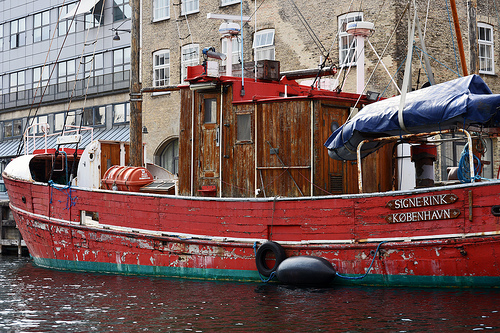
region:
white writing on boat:
[392, 193, 447, 207]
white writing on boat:
[390, 207, 449, 222]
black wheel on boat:
[254, 242, 282, 276]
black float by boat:
[272, 255, 335, 289]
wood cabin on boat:
[177, 73, 387, 198]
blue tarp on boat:
[322, 74, 497, 167]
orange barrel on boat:
[101, 164, 149, 192]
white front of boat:
[75, 140, 105, 194]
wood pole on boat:
[128, 2, 143, 169]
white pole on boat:
[344, 22, 374, 94]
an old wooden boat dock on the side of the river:
[11, 62, 495, 310]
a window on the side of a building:
[8, 19, 24, 49]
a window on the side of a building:
[35, 12, 50, 39]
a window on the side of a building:
[60, 6, 75, 32]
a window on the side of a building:
[8, 72, 25, 97]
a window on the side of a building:
[33, 65, 48, 92]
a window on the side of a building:
[57, 61, 76, 90]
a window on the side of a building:
[84, 53, 104, 85]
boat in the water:
[5, 45, 497, 330]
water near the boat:
[18, 275, 473, 327]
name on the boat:
[384, 199, 464, 218]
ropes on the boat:
[452, 148, 484, 178]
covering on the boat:
[326, 80, 494, 147]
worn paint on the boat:
[100, 233, 205, 270]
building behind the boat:
[143, 0, 495, 171]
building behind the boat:
[8, 7, 134, 137]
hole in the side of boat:
[74, 209, 106, 230]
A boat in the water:
[40, 24, 480, 300]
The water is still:
[41, 290, 139, 311]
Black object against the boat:
[238, 228, 358, 288]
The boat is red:
[15, 175, 498, 300]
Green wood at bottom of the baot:
[18, 233, 498, 304]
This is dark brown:
[153, 62, 378, 211]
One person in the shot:
[413, 127, 496, 189]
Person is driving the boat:
[436, 128, 486, 195]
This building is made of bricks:
[133, 4, 253, 169]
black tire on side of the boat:
[254, 242, 284, 274]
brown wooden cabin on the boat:
[173, 74, 395, 194]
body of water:
[1, 254, 499, 329]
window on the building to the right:
[477, 22, 494, 74]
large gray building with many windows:
[1, 1, 140, 142]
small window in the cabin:
[236, 112, 251, 142]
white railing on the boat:
[23, 122, 94, 153]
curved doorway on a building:
[153, 135, 178, 172]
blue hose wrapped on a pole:
[456, 150, 483, 182]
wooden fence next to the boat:
[0, 217, 28, 258]